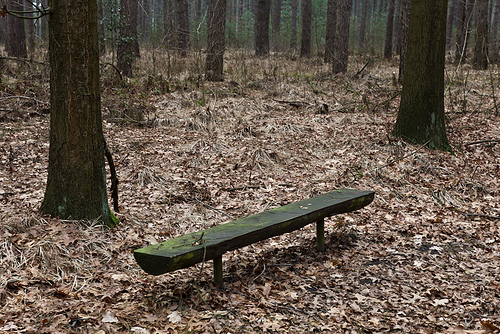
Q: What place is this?
A: It is a forest.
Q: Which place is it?
A: It is a forest.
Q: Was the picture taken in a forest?
A: Yes, it was taken in a forest.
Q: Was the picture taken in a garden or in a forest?
A: It was taken at a forest.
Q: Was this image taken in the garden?
A: No, the picture was taken in the forest.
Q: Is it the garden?
A: No, it is the forest.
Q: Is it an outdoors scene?
A: Yes, it is outdoors.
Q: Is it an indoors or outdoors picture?
A: It is outdoors.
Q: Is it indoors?
A: No, it is outdoors.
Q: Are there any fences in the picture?
A: No, there are no fences.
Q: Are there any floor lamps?
A: No, there are no floor lamps.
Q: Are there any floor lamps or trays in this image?
A: No, there are no floor lamps or trays.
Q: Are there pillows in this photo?
A: No, there are no pillows.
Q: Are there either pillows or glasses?
A: No, there are no pillows or glasses.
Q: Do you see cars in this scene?
A: No, there are no cars.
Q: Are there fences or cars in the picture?
A: No, there are no cars or fences.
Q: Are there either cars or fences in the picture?
A: No, there are no cars or fences.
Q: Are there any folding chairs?
A: No, there are no folding chairs.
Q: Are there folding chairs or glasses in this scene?
A: No, there are no folding chairs or glasses.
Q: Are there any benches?
A: Yes, there is a bench.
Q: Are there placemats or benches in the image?
A: Yes, there is a bench.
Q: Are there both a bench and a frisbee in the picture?
A: No, there is a bench but no frisbees.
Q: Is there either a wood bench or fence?
A: Yes, there is a wood bench.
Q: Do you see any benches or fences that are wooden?
A: Yes, the bench is wooden.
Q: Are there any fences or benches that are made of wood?
A: Yes, the bench is made of wood.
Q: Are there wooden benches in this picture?
A: Yes, there is a wood bench.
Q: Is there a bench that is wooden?
A: Yes, there is a bench that is wooden.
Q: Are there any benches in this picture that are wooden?
A: Yes, there is a bench that is wooden.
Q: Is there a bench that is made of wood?
A: Yes, there is a bench that is made of wood.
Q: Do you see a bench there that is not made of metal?
A: Yes, there is a bench that is made of wood.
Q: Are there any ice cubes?
A: No, there are no ice cubes.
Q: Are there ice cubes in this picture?
A: No, there are no ice cubes.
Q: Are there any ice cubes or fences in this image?
A: No, there are no ice cubes or fences.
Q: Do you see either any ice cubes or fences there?
A: No, there are no ice cubes or fences.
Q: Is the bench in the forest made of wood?
A: Yes, the bench is made of wood.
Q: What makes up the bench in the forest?
A: The bench is made of wood.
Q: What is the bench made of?
A: The bench is made of wood.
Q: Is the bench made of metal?
A: No, the bench is made of wood.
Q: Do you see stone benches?
A: No, there is a bench but it is made of wood.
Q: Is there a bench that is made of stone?
A: No, there is a bench but it is made of wood.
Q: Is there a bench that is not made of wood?
A: No, there is a bench but it is made of wood.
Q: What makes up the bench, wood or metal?
A: The bench is made of wood.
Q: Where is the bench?
A: The bench is in the forest.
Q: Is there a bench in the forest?
A: Yes, there is a bench in the forest.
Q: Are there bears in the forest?
A: No, there is a bench in the forest.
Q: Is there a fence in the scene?
A: No, there are no fences.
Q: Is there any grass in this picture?
A: Yes, there is grass.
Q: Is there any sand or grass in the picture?
A: Yes, there is grass.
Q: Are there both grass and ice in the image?
A: No, there is grass but no ice.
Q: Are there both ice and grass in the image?
A: No, there is grass but no ice.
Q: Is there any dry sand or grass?
A: Yes, there is dry grass.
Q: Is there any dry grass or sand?
A: Yes, there is dry grass.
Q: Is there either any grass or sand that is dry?
A: Yes, the grass is dry.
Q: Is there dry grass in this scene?
A: Yes, there is dry grass.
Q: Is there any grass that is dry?
A: Yes, there is grass that is dry.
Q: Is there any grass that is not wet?
A: Yes, there is dry grass.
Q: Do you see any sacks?
A: No, there are no sacks.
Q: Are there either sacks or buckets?
A: No, there are no sacks or buckets.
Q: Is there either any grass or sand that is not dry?
A: No, there is grass but it is dry.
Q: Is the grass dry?
A: Yes, the grass is dry.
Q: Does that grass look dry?
A: Yes, the grass is dry.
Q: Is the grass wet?
A: No, the grass is dry.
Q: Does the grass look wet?
A: No, the grass is dry.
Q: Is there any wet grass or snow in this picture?
A: No, there is grass but it is dry.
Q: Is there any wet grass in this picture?
A: No, there is grass but it is dry.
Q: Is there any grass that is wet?
A: No, there is grass but it is dry.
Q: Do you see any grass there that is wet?
A: No, there is grass but it is dry.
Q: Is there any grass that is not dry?
A: No, there is grass but it is dry.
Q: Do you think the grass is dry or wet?
A: The grass is dry.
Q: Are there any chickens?
A: No, there are no chickens.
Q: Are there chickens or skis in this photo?
A: No, there are no chickens or skis.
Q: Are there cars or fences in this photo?
A: No, there are no fences or cars.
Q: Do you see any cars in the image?
A: No, there are no cars.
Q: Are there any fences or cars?
A: No, there are no cars or fences.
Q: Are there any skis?
A: No, there are no skis.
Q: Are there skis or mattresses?
A: No, there are no skis or mattresses.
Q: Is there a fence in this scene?
A: No, there are no fences.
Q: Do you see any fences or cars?
A: No, there are no fences or cars.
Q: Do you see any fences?
A: No, there are no fences.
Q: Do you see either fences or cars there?
A: No, there are no fences or cars.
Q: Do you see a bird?
A: No, there are no birds.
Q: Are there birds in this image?
A: No, there are no birds.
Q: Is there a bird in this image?
A: No, there are no birds.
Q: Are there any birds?
A: No, there are no birds.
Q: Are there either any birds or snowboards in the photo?
A: No, there are no birds or snowboards.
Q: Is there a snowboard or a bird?
A: No, there are no birds or snowboards.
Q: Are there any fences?
A: No, there are no fences.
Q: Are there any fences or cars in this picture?
A: No, there are no fences or cars.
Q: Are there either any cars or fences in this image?
A: No, there are no fences or cars.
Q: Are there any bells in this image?
A: No, there are no bells.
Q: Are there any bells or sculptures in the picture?
A: No, there are no bells or sculptures.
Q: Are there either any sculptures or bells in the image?
A: No, there are no bells or sculptures.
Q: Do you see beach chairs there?
A: No, there are no beach chairs.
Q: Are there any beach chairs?
A: No, there are no beach chairs.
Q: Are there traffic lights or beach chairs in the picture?
A: No, there are no beach chairs or traffic lights.